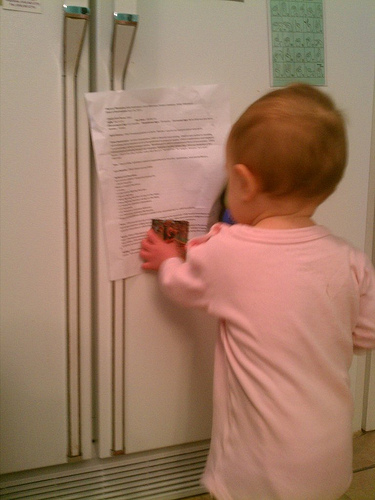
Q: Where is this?
A: Kitchen.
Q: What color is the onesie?
A: Pink.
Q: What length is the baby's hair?
A: Short.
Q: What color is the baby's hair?
A: Blonde.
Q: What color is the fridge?
A: White.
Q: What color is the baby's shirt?
A: White.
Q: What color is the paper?
A: White.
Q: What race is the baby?
A: Caucasian.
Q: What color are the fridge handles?
A: Silver.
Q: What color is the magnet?
A: Brown.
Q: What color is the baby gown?
A: Pink.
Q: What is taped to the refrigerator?
A: A letter.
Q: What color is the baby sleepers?
A: Pink.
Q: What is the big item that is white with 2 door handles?
A: Refrigerator.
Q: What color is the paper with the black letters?
A: White.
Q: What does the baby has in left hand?
A: Picture.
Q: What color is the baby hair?
A: Brown.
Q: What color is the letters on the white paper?
A: Black.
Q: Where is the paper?
A: On the refrigerator door.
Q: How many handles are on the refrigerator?
A: Two.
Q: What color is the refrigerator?
A: White.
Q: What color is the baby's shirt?
A: Pink.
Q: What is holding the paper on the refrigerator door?
A: A magnet.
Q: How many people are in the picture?
A: One.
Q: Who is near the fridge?
A: A baby.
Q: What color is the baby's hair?
A: Light brown.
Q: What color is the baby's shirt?
A: Pink.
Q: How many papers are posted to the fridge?
A: 1.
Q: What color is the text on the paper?
A: Black.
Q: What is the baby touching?
A: A magnet.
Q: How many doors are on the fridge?
A: 2.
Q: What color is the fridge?
A: White.